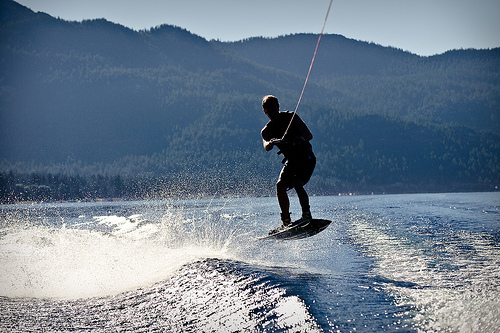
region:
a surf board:
[252, 211, 335, 246]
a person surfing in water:
[247, 80, 336, 245]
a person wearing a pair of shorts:
[256, 81, 320, 229]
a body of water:
[15, 197, 497, 326]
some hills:
[4, 0, 498, 189]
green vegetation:
[4, 2, 494, 214]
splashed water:
[21, 169, 268, 294]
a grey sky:
[21, 0, 499, 60]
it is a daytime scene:
[5, 3, 495, 331]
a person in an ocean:
[11, 84, 495, 331]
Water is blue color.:
[404, 203, 477, 270]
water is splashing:
[18, 225, 131, 285]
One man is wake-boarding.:
[218, 61, 356, 275]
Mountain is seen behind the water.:
[32, 6, 493, 167]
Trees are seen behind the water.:
[6, 166, 198, 199]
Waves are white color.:
[8, 197, 388, 331]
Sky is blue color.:
[351, 6, 492, 39]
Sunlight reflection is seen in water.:
[68, 96, 395, 293]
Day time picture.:
[11, 13, 476, 315]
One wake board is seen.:
[256, 209, 337, 262]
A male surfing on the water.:
[247, 93, 331, 236]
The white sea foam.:
[0, 217, 208, 297]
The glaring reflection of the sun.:
[164, 265, 306, 331]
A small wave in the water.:
[179, 251, 451, 331]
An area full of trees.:
[1, 0, 251, 199]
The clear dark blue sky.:
[346, 0, 498, 33]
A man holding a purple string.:
[258, 0, 347, 152]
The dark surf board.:
[254, 215, 334, 246]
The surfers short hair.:
[261, 92, 280, 117]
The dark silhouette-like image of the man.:
[261, 90, 330, 237]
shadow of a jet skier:
[251, 83, 326, 252]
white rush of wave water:
[17, 218, 184, 288]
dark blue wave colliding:
[174, 248, 326, 331]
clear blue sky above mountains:
[303, 0, 455, 16]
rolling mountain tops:
[19, 15, 449, 75]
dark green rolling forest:
[69, 47, 266, 158]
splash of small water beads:
[133, 134, 274, 242]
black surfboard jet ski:
[256, 210, 366, 259]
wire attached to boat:
[271, 20, 344, 87]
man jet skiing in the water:
[233, 87, 367, 261]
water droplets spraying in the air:
[129, 194, 240, 246]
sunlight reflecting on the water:
[304, 278, 394, 328]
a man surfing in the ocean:
[237, 87, 394, 267]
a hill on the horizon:
[89, 14, 221, 81]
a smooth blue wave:
[201, 252, 287, 318]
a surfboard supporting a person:
[269, 218, 352, 237]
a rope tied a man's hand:
[292, 10, 330, 137]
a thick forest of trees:
[177, 127, 228, 159]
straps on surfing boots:
[280, 209, 337, 221]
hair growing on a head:
[254, 93, 281, 103]